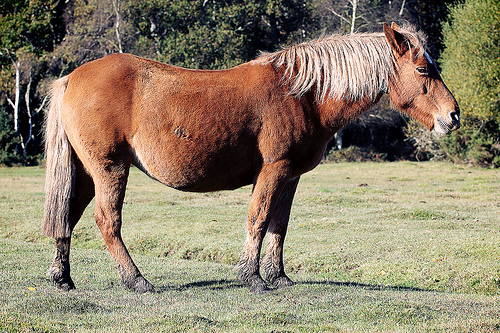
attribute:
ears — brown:
[378, 16, 424, 49]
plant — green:
[40, 19, 470, 308]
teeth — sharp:
[437, 117, 452, 133]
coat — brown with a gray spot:
[167, 109, 242, 159]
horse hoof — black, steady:
[233, 268, 272, 296]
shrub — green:
[126, 2, 284, 64]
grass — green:
[328, 172, 474, 268]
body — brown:
[61, 58, 318, 186]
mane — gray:
[256, 15, 406, 87]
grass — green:
[316, 204, 481, 315]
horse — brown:
[26, 35, 478, 308]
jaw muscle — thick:
[386, 87, 414, 109]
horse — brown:
[41, 17, 461, 297]